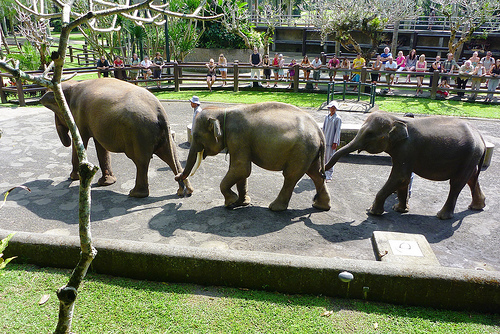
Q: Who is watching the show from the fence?
A: Crowd.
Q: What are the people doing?
A: Watching elephants.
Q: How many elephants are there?
A: Three.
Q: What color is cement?
A: Grey.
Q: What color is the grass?
A: Green.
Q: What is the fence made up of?
A: Wood.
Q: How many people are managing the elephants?
A: Two.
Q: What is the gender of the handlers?
A: Male.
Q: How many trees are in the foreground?
A: One.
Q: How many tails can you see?
A: Three.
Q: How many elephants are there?
A: 3.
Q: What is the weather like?
A: Sunny.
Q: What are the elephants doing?
A: Walking.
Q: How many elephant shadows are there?
A: 3.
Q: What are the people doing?
A: Watching the elephants.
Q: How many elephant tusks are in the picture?
A: 1.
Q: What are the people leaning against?
A: A fence.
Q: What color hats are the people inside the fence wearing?
A: White.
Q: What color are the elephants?
A: Gray.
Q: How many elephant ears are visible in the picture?
A: 3.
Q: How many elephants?
A: Three.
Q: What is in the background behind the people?
A: Building.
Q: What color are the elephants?
A: Grey.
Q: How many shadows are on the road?
A: Three.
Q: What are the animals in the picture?
A: Elephants.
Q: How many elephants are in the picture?
A: Three.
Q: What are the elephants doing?
A: Walking.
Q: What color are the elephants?
A: Gray.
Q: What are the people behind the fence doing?
A: Watching.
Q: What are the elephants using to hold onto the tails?
A: Trunks.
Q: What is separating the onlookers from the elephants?
A: A fence.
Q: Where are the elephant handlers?
A: Next to elephants.